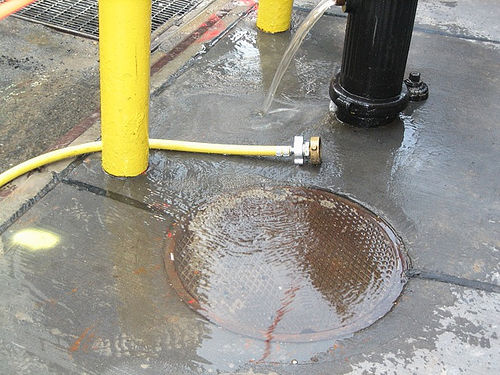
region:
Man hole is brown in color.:
[200, 190, 337, 367]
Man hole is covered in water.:
[173, 210, 357, 328]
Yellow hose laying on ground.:
[8, 113, 275, 191]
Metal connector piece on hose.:
[281, 115, 346, 218]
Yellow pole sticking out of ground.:
[84, 73, 171, 162]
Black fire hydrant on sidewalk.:
[325, 56, 430, 150]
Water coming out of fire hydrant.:
[263, 19, 363, 100]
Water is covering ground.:
[40, 171, 464, 367]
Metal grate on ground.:
[52, 13, 101, 35]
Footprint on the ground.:
[82, 309, 179, 371]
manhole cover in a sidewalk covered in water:
[155, 172, 425, 346]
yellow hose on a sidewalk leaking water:
[5, 117, 360, 195]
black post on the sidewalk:
[321, 11, 442, 129]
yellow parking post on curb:
[81, 28, 183, 190]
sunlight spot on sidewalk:
[4, 222, 76, 266]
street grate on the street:
[11, 4, 123, 34]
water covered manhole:
[161, 171, 425, 352]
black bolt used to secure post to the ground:
[405, 70, 433, 107]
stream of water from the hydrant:
[254, 35, 324, 123]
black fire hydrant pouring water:
[232, 22, 463, 147]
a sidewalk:
[48, 1, 495, 371]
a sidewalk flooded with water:
[58, 3, 475, 359]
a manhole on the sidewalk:
[159, 186, 407, 351]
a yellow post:
[91, 0, 161, 181]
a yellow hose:
[16, 138, 346, 174]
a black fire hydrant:
[330, 3, 452, 130]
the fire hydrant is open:
[272, 3, 445, 145]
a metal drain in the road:
[27, 3, 208, 43]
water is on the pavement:
[85, 158, 482, 365]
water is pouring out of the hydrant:
[263, 0, 365, 147]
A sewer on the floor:
[183, 176, 417, 341]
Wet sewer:
[163, 185, 404, 326]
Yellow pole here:
[63, 2, 174, 196]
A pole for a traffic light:
[341, 2, 441, 147]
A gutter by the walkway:
[1, 0, 243, 62]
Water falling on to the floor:
[256, 0, 408, 131]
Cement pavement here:
[36, 178, 467, 372]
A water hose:
[0, 118, 474, 250]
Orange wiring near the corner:
[0, 2, 158, 90]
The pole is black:
[306, 1, 460, 132]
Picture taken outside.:
[24, 20, 447, 345]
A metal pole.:
[90, 52, 138, 172]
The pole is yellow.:
[78, 24, 150, 204]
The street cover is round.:
[164, 170, 400, 350]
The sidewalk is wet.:
[115, 119, 382, 374]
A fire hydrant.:
[324, 42, 436, 159]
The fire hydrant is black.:
[316, 15, 453, 125]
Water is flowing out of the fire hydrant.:
[241, 16, 362, 83]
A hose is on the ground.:
[171, 129, 326, 174]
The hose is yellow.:
[169, 81, 289, 190]